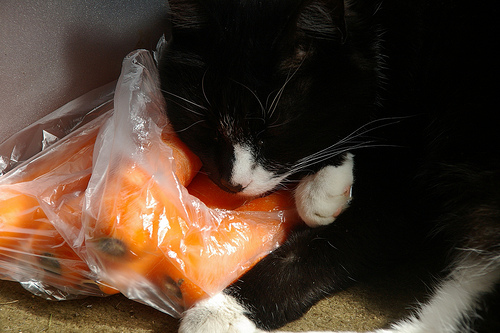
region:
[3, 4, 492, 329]
cat lying on a bag of carrots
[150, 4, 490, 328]
black cat with white markings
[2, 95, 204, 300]
two bags of carrots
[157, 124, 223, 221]
plastic ripped open on bag of carrots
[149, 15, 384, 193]
cat's head resting on carrots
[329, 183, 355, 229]
pink paw pads on cat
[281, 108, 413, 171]
long cat whiskers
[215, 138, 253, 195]
cat's nose is black and white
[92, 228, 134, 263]
end of a carrot seen through a bag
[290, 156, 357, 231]
white paw of a cat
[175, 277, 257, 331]
the legs are black and white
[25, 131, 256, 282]
the carrots are red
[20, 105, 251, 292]
the paper is transparent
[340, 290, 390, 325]
the floor is carpeted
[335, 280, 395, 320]
the floor is brown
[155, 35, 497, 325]
the cat is sleeping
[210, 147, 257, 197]
the nose is black and white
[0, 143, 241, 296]
the carrots are ripe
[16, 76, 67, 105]
the wall is dark grey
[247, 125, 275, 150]
the eyes have tears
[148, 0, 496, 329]
a black and white cat sleeping on some carrots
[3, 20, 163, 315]
a plastic bag of carrots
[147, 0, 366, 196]
the head of a cat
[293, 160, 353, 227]
the paw of a cat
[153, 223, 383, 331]
the leg of a cat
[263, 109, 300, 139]
the eye of a cat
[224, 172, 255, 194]
the nose of a cat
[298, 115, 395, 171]
the whiskers of a cat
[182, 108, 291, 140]
the eyes of a cat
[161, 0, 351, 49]
the ears of a cat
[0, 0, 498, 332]
Cat lying on a bag of carrots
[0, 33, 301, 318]
Bag of large carrots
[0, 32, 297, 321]
Plastic produce bag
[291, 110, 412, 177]
White cat whiskers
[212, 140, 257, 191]
Half black half white cat nose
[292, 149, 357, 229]
White cat paw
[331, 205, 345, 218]
Pink paw pad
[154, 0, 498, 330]
Black and white cat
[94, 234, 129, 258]
Brown stem end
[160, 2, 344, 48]
Black cat ears with white ear hair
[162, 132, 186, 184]
part of the carrot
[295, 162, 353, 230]
white paws on the kitty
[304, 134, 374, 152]
whiskers on the cat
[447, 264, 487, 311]
white on the cat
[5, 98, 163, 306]
carrots in a bag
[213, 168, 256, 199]
nose of the cat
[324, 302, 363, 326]
dirt the cat is laying on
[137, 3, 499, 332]
cat laying on a bag of carrots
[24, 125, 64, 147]
top of the plastic baggy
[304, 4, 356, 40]
ear of the cat